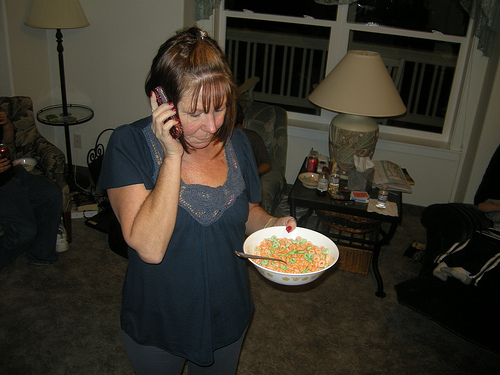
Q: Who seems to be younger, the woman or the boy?
A: The boy is younger than the woman.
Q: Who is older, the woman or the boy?
A: The woman is older than the boy.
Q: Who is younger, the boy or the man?
A: The boy is younger than the man.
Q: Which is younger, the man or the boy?
A: The boy is younger than the man.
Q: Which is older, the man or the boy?
A: The man is older than the boy.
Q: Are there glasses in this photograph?
A: No, there are no glasses.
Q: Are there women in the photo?
A: Yes, there is a woman.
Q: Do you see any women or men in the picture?
A: Yes, there is a woman.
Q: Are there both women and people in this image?
A: Yes, there are both a woman and people.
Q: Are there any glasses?
A: No, there are no glasses.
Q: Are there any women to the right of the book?
A: Yes, there is a woman to the right of the book.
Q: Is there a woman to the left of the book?
A: No, the woman is to the right of the book.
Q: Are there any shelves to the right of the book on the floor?
A: No, there is a woman to the right of the book.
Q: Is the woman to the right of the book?
A: Yes, the woman is to the right of the book.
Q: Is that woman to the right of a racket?
A: No, the woman is to the right of the book.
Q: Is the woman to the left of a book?
A: No, the woman is to the right of a book.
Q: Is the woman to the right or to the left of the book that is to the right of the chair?
A: The woman is to the right of the book.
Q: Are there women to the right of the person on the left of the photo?
A: Yes, there is a woman to the right of the person.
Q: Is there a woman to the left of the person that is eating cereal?
A: No, the woman is to the right of the person.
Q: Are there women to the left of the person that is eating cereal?
A: No, the woman is to the right of the person.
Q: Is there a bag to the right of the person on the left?
A: No, there is a woman to the right of the person.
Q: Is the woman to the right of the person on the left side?
A: Yes, the woman is to the right of the person.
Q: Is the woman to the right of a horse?
A: No, the woman is to the right of the person.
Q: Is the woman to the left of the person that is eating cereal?
A: No, the woman is to the right of the person.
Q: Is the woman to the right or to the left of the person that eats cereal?
A: The woman is to the right of the person.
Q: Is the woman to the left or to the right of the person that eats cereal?
A: The woman is to the right of the person.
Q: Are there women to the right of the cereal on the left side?
A: Yes, there is a woman to the right of the cereal.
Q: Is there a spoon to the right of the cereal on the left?
A: No, there is a woman to the right of the cereal.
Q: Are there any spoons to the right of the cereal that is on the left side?
A: No, there is a woman to the right of the cereal.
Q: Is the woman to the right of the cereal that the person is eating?
A: Yes, the woman is to the right of the cereal.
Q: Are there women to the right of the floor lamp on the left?
A: Yes, there is a woman to the right of the floor lamp.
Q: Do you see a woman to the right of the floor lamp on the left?
A: Yes, there is a woman to the right of the floor lamp.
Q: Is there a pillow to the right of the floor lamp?
A: No, there is a woman to the right of the floor lamp.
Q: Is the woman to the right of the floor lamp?
A: Yes, the woman is to the right of the floor lamp.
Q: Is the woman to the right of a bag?
A: No, the woman is to the right of the floor lamp.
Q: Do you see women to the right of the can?
A: No, the woman is to the left of the can.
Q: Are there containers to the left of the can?
A: No, there is a woman to the left of the can.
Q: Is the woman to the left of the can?
A: Yes, the woman is to the left of the can.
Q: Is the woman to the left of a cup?
A: No, the woman is to the left of the can.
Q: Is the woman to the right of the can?
A: No, the woman is to the left of the can.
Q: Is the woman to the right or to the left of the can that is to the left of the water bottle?
A: The woman is to the left of the can.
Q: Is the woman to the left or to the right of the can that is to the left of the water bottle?
A: The woman is to the left of the can.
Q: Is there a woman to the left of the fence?
A: Yes, there is a woman to the left of the fence.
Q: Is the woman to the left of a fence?
A: Yes, the woman is to the left of a fence.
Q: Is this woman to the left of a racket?
A: No, the woman is to the left of a fence.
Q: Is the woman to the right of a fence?
A: No, the woman is to the left of a fence.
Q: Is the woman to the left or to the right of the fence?
A: The woman is to the left of the fence.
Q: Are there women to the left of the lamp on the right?
A: Yes, there is a woman to the left of the lamp.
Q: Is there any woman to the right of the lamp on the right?
A: No, the woman is to the left of the lamp.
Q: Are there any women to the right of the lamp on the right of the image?
A: No, the woman is to the left of the lamp.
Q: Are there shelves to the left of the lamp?
A: No, there is a woman to the left of the lamp.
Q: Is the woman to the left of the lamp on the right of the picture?
A: Yes, the woman is to the left of the lamp.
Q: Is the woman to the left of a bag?
A: No, the woman is to the left of the lamp.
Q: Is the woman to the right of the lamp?
A: No, the woman is to the left of the lamp.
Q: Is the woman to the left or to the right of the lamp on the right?
A: The woman is to the left of the lamp.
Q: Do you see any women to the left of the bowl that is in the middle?
A: Yes, there is a woman to the left of the bowl.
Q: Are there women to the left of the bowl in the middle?
A: Yes, there is a woman to the left of the bowl.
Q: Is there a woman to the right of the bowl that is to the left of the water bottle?
A: No, the woman is to the left of the bowl.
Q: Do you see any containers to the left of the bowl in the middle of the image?
A: No, there is a woman to the left of the bowl.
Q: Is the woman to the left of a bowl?
A: Yes, the woman is to the left of a bowl.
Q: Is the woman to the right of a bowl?
A: No, the woman is to the left of a bowl.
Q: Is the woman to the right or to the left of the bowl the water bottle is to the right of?
A: The woman is to the left of the bowl.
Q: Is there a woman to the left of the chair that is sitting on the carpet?
A: Yes, there is a woman to the left of the chair.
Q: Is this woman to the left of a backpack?
A: No, the woman is to the left of the chair.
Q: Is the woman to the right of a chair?
A: No, the woman is to the left of a chair.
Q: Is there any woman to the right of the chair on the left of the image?
A: Yes, there is a woman to the right of the chair.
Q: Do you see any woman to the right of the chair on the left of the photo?
A: Yes, there is a woman to the right of the chair.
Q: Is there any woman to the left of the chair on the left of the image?
A: No, the woman is to the right of the chair.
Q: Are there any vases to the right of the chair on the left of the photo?
A: No, there is a woman to the right of the chair.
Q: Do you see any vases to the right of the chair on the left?
A: No, there is a woman to the right of the chair.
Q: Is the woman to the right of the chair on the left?
A: Yes, the woman is to the right of the chair.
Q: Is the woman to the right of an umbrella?
A: No, the woman is to the right of the chair.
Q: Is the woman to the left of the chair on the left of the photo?
A: No, the woman is to the right of the chair.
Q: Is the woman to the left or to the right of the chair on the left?
A: The woman is to the right of the chair.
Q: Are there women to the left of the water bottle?
A: Yes, there is a woman to the left of the water bottle.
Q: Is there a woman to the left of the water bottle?
A: Yes, there is a woman to the left of the water bottle.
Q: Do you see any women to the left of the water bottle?
A: Yes, there is a woman to the left of the water bottle.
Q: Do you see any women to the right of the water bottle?
A: No, the woman is to the left of the water bottle.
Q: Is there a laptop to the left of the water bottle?
A: No, there is a woman to the left of the water bottle.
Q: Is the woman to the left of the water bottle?
A: Yes, the woman is to the left of the water bottle.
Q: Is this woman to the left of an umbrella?
A: No, the woman is to the left of the water bottle.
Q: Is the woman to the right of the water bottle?
A: No, the woman is to the left of the water bottle.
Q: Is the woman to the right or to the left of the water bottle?
A: The woman is to the left of the water bottle.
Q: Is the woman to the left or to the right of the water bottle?
A: The woman is to the left of the water bottle.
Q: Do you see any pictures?
A: No, there are no pictures.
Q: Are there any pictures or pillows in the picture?
A: No, there are no pictures or pillows.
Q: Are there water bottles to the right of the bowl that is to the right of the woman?
A: Yes, there is a water bottle to the right of the bowl.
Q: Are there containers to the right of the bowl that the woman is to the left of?
A: No, there is a water bottle to the right of the bowl.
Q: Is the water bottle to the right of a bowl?
A: Yes, the water bottle is to the right of a bowl.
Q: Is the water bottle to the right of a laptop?
A: No, the water bottle is to the right of a bowl.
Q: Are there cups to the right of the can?
A: No, there is a water bottle to the right of the can.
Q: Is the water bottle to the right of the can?
A: Yes, the water bottle is to the right of the can.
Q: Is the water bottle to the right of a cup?
A: No, the water bottle is to the right of the can.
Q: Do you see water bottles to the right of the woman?
A: Yes, there is a water bottle to the right of the woman.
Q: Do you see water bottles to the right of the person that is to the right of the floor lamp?
A: Yes, there is a water bottle to the right of the woman.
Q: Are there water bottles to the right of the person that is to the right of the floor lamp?
A: Yes, there is a water bottle to the right of the woman.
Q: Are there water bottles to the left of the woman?
A: No, the water bottle is to the right of the woman.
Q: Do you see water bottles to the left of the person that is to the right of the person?
A: No, the water bottle is to the right of the woman.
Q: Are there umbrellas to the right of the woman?
A: No, there is a water bottle to the right of the woman.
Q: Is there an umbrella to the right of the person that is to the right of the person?
A: No, there is a water bottle to the right of the woman.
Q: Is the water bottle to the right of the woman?
A: Yes, the water bottle is to the right of the woman.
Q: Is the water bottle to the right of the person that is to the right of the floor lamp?
A: Yes, the water bottle is to the right of the woman.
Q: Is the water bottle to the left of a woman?
A: No, the water bottle is to the right of a woman.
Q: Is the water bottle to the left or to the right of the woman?
A: The water bottle is to the right of the woman.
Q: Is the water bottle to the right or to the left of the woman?
A: The water bottle is to the right of the woman.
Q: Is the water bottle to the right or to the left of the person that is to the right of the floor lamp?
A: The water bottle is to the right of the woman.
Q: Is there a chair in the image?
A: Yes, there is a chair.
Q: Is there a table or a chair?
A: Yes, there is a chair.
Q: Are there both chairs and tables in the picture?
A: Yes, there are both a chair and a table.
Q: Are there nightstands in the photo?
A: No, there are no nightstands.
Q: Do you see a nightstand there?
A: No, there are no nightstands.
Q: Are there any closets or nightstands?
A: No, there are no nightstands or closets.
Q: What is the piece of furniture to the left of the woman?
A: The piece of furniture is a chair.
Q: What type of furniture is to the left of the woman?
A: The piece of furniture is a chair.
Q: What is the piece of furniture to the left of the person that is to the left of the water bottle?
A: The piece of furniture is a chair.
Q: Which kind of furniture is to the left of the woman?
A: The piece of furniture is a chair.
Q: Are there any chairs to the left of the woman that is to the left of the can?
A: Yes, there is a chair to the left of the woman.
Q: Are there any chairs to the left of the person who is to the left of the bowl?
A: Yes, there is a chair to the left of the woman.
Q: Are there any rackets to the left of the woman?
A: No, there is a chair to the left of the woman.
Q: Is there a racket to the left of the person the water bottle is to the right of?
A: No, there is a chair to the left of the woman.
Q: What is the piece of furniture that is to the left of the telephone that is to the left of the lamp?
A: The piece of furniture is a chair.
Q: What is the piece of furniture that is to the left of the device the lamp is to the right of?
A: The piece of furniture is a chair.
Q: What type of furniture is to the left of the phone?
A: The piece of furniture is a chair.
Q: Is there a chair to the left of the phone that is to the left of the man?
A: Yes, there is a chair to the left of the phone.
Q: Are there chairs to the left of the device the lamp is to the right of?
A: Yes, there is a chair to the left of the phone.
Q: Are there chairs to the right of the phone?
A: No, the chair is to the left of the phone.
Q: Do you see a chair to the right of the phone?
A: No, the chair is to the left of the phone.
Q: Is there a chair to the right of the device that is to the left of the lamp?
A: No, the chair is to the left of the phone.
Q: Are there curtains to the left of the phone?
A: No, there is a chair to the left of the phone.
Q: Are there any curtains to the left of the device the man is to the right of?
A: No, there is a chair to the left of the phone.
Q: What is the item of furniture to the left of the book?
A: The piece of furniture is a chair.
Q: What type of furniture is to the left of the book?
A: The piece of furniture is a chair.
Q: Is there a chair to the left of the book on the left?
A: Yes, there is a chair to the left of the book.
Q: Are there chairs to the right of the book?
A: No, the chair is to the left of the book.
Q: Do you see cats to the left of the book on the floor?
A: No, there is a chair to the left of the book.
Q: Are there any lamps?
A: Yes, there is a lamp.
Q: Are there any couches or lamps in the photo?
A: Yes, there is a lamp.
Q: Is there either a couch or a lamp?
A: Yes, there is a lamp.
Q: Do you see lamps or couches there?
A: Yes, there is a lamp.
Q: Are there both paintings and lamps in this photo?
A: No, there is a lamp but no paintings.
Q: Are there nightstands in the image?
A: No, there are no nightstands.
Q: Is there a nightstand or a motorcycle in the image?
A: No, there are no nightstands or motorcycles.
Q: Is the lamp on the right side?
A: Yes, the lamp is on the right of the image.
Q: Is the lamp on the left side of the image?
A: No, the lamp is on the right of the image.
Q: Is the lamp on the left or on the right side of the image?
A: The lamp is on the right of the image.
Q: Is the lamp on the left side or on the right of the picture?
A: The lamp is on the right of the image.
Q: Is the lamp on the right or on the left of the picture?
A: The lamp is on the right of the image.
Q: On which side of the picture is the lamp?
A: The lamp is on the right of the image.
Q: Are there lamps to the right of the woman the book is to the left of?
A: Yes, there is a lamp to the right of the woman.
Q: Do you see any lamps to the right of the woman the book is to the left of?
A: Yes, there is a lamp to the right of the woman.